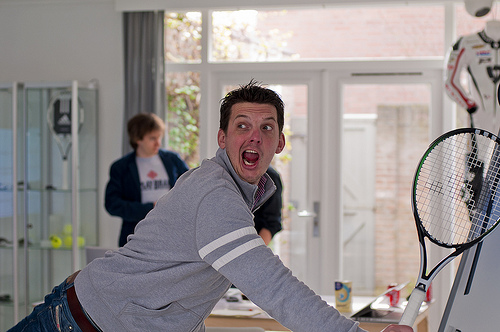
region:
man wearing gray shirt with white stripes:
[24, 83, 384, 330]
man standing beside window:
[99, 110, 184, 237]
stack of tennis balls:
[48, 217, 83, 250]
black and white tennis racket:
[390, 122, 498, 323]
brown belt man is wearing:
[66, 274, 98, 330]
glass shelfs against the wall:
[7, 82, 88, 330]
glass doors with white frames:
[210, 72, 438, 299]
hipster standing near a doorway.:
[96, 105, 201, 247]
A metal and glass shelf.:
[0, 80, 102, 327]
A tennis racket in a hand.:
[394, 128, 496, 325]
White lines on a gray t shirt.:
[195, 225, 269, 273]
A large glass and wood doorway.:
[204, 62, 437, 328]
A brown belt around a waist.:
[64, 269, 103, 327]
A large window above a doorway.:
[201, 3, 446, 64]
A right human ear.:
[215, 125, 229, 148]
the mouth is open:
[234, 147, 262, 169]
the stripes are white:
[193, 228, 275, 275]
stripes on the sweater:
[117, 167, 297, 330]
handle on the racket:
[401, 132, 490, 322]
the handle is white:
[403, 260, 415, 330]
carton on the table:
[327, 282, 355, 314]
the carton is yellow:
[329, 275, 352, 317]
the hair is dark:
[222, 78, 273, 108]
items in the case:
[4, 80, 90, 305]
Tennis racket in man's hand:
[394, 130, 499, 329]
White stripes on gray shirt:
[192, 226, 262, 263]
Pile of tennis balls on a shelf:
[45, 227, 84, 248]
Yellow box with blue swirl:
[332, 278, 351, 313]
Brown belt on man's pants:
[62, 276, 94, 330]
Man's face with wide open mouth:
[221, 100, 283, 181]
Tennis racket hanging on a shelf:
[43, 93, 83, 187]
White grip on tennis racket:
[397, 284, 426, 321]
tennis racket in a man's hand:
[400, 125, 498, 330]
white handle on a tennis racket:
[399, 281, 428, 329]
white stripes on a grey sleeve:
[188, 223, 273, 272]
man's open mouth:
[238, 146, 261, 168]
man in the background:
[102, 105, 197, 253]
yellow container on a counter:
[330, 275, 355, 312]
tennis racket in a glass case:
[42, 89, 84, 191]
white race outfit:
[441, 26, 498, 190]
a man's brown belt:
[61, 263, 102, 330]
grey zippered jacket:
[67, 150, 372, 330]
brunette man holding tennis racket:
[70, 64, 493, 325]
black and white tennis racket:
[372, 112, 498, 327]